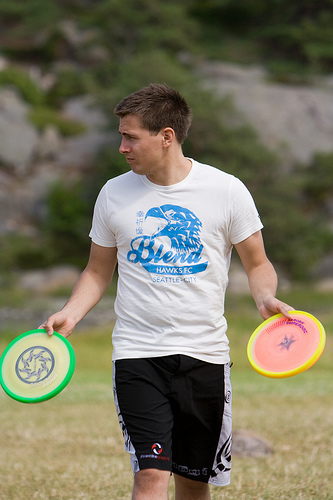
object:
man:
[38, 84, 296, 500]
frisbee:
[0, 328, 76, 403]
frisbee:
[246, 310, 326, 379]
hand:
[257, 297, 298, 323]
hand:
[38, 312, 76, 339]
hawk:
[144, 205, 203, 250]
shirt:
[88, 157, 264, 367]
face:
[117, 115, 155, 175]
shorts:
[112, 353, 233, 488]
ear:
[162, 127, 175, 149]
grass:
[0, 294, 333, 500]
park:
[0, 1, 332, 499]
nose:
[118, 138, 131, 155]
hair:
[114, 82, 192, 145]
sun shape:
[15, 345, 54, 384]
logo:
[152, 442, 162, 456]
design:
[277, 333, 296, 352]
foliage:
[0, 1, 333, 278]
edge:
[133, 459, 174, 474]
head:
[113, 84, 192, 174]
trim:
[246, 310, 327, 380]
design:
[127, 203, 208, 275]